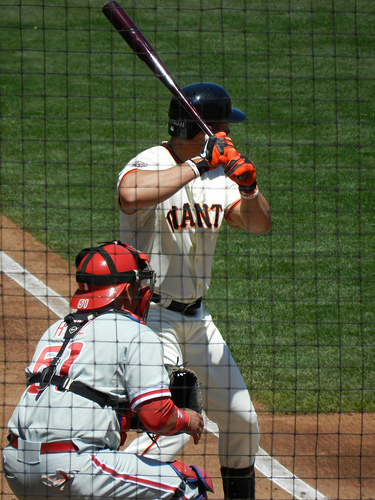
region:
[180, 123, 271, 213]
player wearing the gloves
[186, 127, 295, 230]
player wearing the gloves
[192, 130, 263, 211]
player wearing the gloves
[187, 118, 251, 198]
player wearing the gloves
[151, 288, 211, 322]
the belt is black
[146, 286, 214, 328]
the belt is black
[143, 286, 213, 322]
the belt is black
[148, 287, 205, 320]
the belt is black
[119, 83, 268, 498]
batter in the batter's box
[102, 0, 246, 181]
wooden baseball bat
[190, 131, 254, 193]
orange and black batting gloves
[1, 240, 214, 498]
catcher crouching behind the batter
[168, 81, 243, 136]
batting helmet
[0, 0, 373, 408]
grass of the infield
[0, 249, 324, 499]
white foul line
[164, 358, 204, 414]
black catcher's mitt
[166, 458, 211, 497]
red shinguard with blue trim on the catcher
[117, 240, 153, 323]
red catcher's mask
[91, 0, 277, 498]
Baseball player holding a bat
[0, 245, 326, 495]
White line on the dirt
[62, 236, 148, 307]
The helmet is red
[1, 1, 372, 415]
Green grass on the field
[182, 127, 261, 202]
A pair of batting gloves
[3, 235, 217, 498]
The catcher is crouched down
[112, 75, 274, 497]
Batter wearing a white uniform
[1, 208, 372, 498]
Brown dirt on the field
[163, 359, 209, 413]
A black leather glove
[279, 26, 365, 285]
The grass is short and green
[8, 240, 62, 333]
The line on the ground is white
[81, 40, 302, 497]
The man is playing baseball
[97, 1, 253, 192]
The man is holding a baseball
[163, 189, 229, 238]
The logo on the shirt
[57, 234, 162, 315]
The man is wearing a helmet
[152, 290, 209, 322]
The man is wearing a black belt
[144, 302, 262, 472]
The man is wearing white pants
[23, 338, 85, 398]
The number on the jersey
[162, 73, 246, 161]
the helmet is black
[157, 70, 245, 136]
the helmet is black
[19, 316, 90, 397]
jersey number is 61